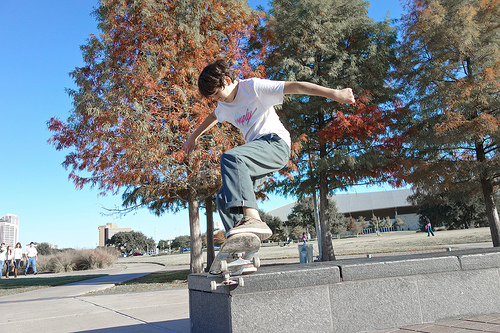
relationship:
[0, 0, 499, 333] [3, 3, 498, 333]
scene in scene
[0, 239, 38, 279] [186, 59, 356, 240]
people watching boy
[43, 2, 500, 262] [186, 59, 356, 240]
trees behind boy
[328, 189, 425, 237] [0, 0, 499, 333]
house behind scene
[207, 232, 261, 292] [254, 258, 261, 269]
skateboard has wheel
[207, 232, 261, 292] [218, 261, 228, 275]
skateboard has wheel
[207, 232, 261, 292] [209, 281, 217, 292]
skateboard has wheel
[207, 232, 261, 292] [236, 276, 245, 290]
skateboard has wheel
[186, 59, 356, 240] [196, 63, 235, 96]
boy has hair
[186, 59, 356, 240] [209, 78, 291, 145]
boy has shirt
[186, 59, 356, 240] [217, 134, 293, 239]
boy has pants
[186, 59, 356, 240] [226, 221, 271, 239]
boy has shoes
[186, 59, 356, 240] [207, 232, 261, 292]
boy on top of skateboard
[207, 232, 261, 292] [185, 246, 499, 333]
skateboard on top of wall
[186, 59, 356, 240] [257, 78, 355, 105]
boy has arm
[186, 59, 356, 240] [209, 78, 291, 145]
boy wearing shirt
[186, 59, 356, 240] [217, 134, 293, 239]
boy wearing pants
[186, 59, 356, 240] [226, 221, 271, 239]
boy wearing shoes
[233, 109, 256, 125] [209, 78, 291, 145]
lettering printed on shirt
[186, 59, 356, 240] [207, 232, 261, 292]
boy balancing on skateboard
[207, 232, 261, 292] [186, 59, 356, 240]
skateboard under boy